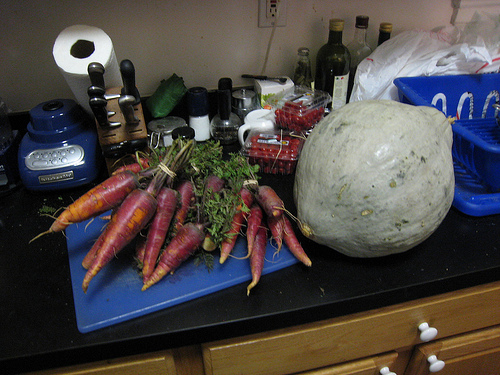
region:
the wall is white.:
[3, 4, 281, 109]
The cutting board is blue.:
[45, 175, 293, 333]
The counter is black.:
[4, 97, 494, 324]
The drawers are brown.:
[210, 282, 495, 373]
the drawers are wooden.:
[207, 287, 498, 372]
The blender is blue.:
[18, 84, 100, 188]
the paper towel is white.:
[50, 17, 121, 110]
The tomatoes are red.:
[245, 117, 295, 172]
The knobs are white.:
[415, 317, 445, 372]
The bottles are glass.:
[294, 7, 393, 98]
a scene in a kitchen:
[29, 17, 497, 338]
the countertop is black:
[47, 70, 447, 325]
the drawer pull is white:
[415, 320, 473, 347]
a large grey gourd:
[251, 73, 483, 255]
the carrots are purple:
[48, 120, 313, 257]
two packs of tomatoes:
[231, 80, 367, 222]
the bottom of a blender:
[13, 84, 115, 206]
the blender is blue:
[10, 78, 138, 204]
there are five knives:
[73, 51, 204, 156]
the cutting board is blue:
[26, 85, 332, 333]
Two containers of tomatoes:
[236, 86, 336, 185]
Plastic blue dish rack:
[395, 75, 498, 220]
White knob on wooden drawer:
[385, 317, 458, 342]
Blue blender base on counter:
[15, 91, 99, 191]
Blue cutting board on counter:
[40, 219, 241, 334]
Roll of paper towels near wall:
[43, 23, 131, 109]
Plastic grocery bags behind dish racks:
[342, 16, 499, 100]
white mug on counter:
[236, 104, 282, 151]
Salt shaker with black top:
[182, 75, 212, 145]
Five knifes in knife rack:
[79, 51, 154, 163]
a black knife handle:
[116, 55, 143, 105]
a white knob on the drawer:
[415, 320, 438, 344]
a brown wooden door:
[201, 282, 498, 373]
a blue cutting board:
[61, 214, 301, 334]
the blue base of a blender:
[14, 92, 101, 195]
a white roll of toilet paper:
[52, 17, 125, 114]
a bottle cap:
[324, 14, 346, 34]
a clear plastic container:
[266, 80, 337, 137]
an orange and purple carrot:
[36, 165, 142, 236]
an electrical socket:
[255, 0, 291, 30]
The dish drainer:
[382, 61, 498, 235]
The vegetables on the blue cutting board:
[35, 142, 318, 301]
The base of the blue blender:
[12, 93, 98, 198]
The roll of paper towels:
[50, 21, 125, 111]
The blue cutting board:
[61, 196, 306, 330]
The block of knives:
[83, 59, 150, 168]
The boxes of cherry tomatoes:
[240, 84, 330, 181]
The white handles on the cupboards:
[371, 318, 443, 373]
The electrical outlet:
[261, 1, 288, 33]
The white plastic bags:
[351, 14, 498, 123]